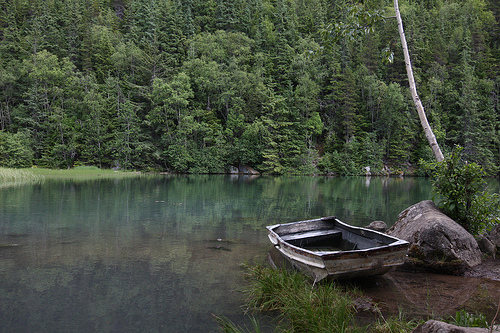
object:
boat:
[266, 213, 411, 284]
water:
[0, 168, 499, 330]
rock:
[394, 200, 486, 277]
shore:
[285, 256, 493, 320]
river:
[0, 165, 497, 332]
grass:
[238, 259, 371, 331]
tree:
[329, 63, 361, 169]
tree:
[251, 92, 303, 175]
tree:
[143, 75, 181, 171]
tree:
[31, 52, 81, 167]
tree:
[450, 39, 495, 215]